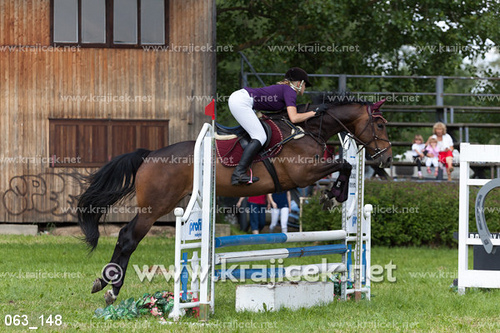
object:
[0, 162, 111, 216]
graffiti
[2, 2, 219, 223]
building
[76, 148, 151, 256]
tail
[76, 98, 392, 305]
horse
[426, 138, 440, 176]
child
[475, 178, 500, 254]
horseshoe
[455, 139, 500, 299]
fence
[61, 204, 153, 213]
logo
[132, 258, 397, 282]
logo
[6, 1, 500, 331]
picture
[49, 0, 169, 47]
window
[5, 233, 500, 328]
grass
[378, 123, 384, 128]
eye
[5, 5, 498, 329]
competition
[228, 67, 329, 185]
girl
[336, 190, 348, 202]
hooves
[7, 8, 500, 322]
air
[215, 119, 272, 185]
saddle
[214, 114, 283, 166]
blanket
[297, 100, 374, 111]
mane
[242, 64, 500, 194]
stands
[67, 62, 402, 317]
jump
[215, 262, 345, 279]
rails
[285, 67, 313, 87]
helmet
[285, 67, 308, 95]
head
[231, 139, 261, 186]
boot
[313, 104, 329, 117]
glove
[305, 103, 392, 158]
rein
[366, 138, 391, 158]
bridge piece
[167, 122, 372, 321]
obstacle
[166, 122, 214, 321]
flap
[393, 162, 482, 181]
bench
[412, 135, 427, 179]
kids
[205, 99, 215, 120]
flag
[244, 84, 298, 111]
shirt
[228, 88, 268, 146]
pants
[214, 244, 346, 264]
rail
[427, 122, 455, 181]
person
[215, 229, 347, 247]
poles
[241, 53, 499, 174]
bleachers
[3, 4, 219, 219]
house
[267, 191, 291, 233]
person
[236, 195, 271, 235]
person